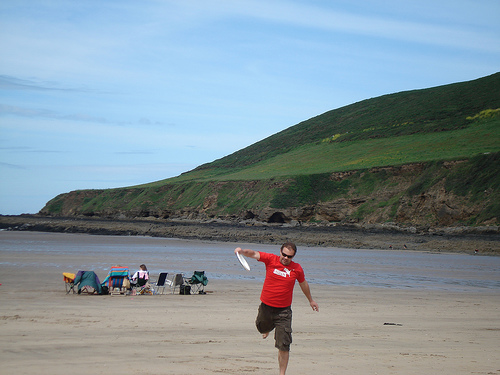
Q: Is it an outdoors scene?
A: Yes, it is outdoors.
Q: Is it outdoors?
A: Yes, it is outdoors.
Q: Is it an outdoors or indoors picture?
A: It is outdoors.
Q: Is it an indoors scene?
A: No, it is outdoors.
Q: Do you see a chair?
A: Yes, there is a chair.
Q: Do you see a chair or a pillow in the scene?
A: Yes, there is a chair.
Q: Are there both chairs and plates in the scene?
A: No, there is a chair but no plates.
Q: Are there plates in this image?
A: No, there are no plates.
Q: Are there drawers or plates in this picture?
A: No, there are no plates or drawers.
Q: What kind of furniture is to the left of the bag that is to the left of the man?
A: The piece of furniture is a chair.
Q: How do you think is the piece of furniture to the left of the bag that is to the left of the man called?
A: The piece of furniture is a chair.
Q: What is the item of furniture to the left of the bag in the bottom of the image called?
A: The piece of furniture is a chair.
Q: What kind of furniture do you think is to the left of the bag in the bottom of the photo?
A: The piece of furniture is a chair.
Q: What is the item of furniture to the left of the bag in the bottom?
A: The piece of furniture is a chair.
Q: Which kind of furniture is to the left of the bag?
A: The piece of furniture is a chair.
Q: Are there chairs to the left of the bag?
A: Yes, there is a chair to the left of the bag.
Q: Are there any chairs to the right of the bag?
A: No, the chair is to the left of the bag.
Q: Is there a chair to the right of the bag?
A: No, the chair is to the left of the bag.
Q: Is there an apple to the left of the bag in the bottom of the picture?
A: No, there is a chair to the left of the bag.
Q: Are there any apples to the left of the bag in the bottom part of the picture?
A: No, there is a chair to the left of the bag.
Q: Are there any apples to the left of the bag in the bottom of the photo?
A: No, there is a chair to the left of the bag.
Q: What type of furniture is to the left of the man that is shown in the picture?
A: The piece of furniture is a chair.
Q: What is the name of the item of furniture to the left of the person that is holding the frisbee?
A: The piece of furniture is a chair.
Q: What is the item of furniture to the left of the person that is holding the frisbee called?
A: The piece of furniture is a chair.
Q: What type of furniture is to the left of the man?
A: The piece of furniture is a chair.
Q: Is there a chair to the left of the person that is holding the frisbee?
A: Yes, there is a chair to the left of the man.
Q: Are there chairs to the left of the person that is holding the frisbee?
A: Yes, there is a chair to the left of the man.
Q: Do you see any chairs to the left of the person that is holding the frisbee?
A: Yes, there is a chair to the left of the man.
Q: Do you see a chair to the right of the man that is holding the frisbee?
A: No, the chair is to the left of the man.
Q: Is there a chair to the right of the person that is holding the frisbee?
A: No, the chair is to the left of the man.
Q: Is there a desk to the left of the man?
A: No, there is a chair to the left of the man.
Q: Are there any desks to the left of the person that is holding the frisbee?
A: No, there is a chair to the left of the man.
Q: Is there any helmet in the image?
A: No, there are no helmets.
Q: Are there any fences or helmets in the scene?
A: No, there are no helmets or fences.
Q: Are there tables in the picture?
A: No, there are no tables.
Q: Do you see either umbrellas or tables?
A: No, there are no tables or umbrellas.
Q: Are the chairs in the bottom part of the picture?
A: Yes, the chairs are in the bottom of the image.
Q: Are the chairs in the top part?
A: No, the chairs are in the bottom of the image.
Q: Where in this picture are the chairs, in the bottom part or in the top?
A: The chairs are in the bottom of the image.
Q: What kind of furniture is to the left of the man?
A: The pieces of furniture are chairs.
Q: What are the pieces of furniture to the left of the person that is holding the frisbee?
A: The pieces of furniture are chairs.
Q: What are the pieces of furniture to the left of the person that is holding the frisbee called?
A: The pieces of furniture are chairs.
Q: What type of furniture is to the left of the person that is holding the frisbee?
A: The pieces of furniture are chairs.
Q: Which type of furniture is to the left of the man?
A: The pieces of furniture are chairs.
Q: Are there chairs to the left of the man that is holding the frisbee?
A: Yes, there are chairs to the left of the man.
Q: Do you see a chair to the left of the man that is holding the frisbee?
A: Yes, there are chairs to the left of the man.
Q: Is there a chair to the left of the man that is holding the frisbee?
A: Yes, there are chairs to the left of the man.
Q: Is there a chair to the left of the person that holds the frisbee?
A: Yes, there are chairs to the left of the man.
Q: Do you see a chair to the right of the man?
A: No, the chairs are to the left of the man.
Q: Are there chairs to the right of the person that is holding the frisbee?
A: No, the chairs are to the left of the man.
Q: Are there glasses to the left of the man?
A: No, there are chairs to the left of the man.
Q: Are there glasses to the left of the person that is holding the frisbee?
A: No, there are chairs to the left of the man.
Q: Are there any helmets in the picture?
A: No, there are no helmets.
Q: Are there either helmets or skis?
A: No, there are no helmets or skis.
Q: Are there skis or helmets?
A: No, there are no helmets or skis.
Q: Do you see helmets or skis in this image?
A: No, there are no helmets or skis.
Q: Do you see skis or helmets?
A: No, there are no helmets or skis.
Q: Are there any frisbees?
A: Yes, there is a frisbee.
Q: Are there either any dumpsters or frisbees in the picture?
A: Yes, there is a frisbee.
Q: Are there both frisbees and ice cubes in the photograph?
A: No, there is a frisbee but no ice cubes.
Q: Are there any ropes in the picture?
A: No, there are no ropes.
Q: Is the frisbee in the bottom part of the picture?
A: Yes, the frisbee is in the bottom of the image.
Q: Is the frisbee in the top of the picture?
A: No, the frisbee is in the bottom of the image.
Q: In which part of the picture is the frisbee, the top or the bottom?
A: The frisbee is in the bottom of the image.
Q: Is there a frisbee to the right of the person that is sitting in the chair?
A: Yes, there is a frisbee to the right of the person.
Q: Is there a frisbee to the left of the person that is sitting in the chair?
A: No, the frisbee is to the right of the person.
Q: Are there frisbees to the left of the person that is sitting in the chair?
A: No, the frisbee is to the right of the person.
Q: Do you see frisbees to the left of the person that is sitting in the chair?
A: No, the frisbee is to the right of the person.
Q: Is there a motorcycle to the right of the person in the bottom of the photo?
A: No, there is a frisbee to the right of the person.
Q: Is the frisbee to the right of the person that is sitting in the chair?
A: Yes, the frisbee is to the right of the person.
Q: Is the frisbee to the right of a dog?
A: No, the frisbee is to the right of the person.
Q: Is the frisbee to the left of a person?
A: No, the frisbee is to the right of a person.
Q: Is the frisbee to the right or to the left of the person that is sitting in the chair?
A: The frisbee is to the right of the person.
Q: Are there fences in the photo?
A: No, there are no fences.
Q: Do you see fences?
A: No, there are no fences.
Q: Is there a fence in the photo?
A: No, there are no fences.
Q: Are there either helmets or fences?
A: No, there are no fences or helmets.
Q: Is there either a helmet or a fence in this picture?
A: No, there are no fences or helmets.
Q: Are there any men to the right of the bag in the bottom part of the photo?
A: Yes, there is a man to the right of the bag.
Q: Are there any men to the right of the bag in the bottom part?
A: Yes, there is a man to the right of the bag.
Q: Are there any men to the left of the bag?
A: No, the man is to the right of the bag.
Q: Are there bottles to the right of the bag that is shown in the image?
A: No, there is a man to the right of the bag.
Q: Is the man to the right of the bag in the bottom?
A: Yes, the man is to the right of the bag.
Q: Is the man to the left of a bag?
A: No, the man is to the right of a bag.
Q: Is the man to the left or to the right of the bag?
A: The man is to the right of the bag.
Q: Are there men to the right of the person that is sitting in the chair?
A: Yes, there is a man to the right of the person.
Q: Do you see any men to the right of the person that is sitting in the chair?
A: Yes, there is a man to the right of the person.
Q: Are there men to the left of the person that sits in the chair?
A: No, the man is to the right of the person.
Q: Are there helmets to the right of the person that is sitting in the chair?
A: No, there is a man to the right of the person.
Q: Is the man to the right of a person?
A: Yes, the man is to the right of a person.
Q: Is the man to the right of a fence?
A: No, the man is to the right of a person.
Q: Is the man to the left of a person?
A: No, the man is to the right of a person.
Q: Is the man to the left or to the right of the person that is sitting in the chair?
A: The man is to the right of the person.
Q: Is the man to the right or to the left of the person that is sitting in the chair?
A: The man is to the right of the person.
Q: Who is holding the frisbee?
A: The man is holding the frisbee.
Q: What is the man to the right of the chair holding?
A: The man is holding the frisbee.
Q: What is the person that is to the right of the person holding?
A: The man is holding the frisbee.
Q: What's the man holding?
A: The man is holding the frisbee.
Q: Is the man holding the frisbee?
A: Yes, the man is holding the frisbee.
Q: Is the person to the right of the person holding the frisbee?
A: Yes, the man is holding the frisbee.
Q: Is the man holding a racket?
A: No, the man is holding the frisbee.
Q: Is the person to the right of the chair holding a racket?
A: No, the man is holding the frisbee.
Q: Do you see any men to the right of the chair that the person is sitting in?
A: Yes, there is a man to the right of the chair.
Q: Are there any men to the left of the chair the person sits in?
A: No, the man is to the right of the chair.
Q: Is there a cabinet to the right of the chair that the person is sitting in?
A: No, there is a man to the right of the chair.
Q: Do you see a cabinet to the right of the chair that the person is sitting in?
A: No, there is a man to the right of the chair.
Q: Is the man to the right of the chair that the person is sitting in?
A: Yes, the man is to the right of the chair.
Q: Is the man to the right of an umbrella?
A: No, the man is to the right of the chair.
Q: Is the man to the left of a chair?
A: No, the man is to the right of a chair.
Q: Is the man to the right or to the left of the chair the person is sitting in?
A: The man is to the right of the chair.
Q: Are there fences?
A: No, there are no fences.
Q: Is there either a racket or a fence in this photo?
A: No, there are no fences or rackets.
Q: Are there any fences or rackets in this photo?
A: No, there are no fences or rackets.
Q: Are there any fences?
A: No, there are no fences.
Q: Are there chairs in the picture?
A: Yes, there is a chair.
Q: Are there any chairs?
A: Yes, there is a chair.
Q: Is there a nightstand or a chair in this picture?
A: Yes, there is a chair.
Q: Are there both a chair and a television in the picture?
A: No, there is a chair but no televisions.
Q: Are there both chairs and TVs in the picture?
A: No, there is a chair but no televisions.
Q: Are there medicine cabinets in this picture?
A: No, there are no medicine cabinets.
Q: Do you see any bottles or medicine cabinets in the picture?
A: No, there are no medicine cabinets or bottles.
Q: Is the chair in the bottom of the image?
A: Yes, the chair is in the bottom of the image.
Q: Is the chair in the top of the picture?
A: No, the chair is in the bottom of the image.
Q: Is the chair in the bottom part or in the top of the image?
A: The chair is in the bottom of the image.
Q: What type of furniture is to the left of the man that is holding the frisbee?
A: The piece of furniture is a chair.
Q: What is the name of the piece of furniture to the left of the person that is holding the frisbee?
A: The piece of furniture is a chair.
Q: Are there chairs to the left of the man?
A: Yes, there is a chair to the left of the man.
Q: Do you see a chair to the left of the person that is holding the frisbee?
A: Yes, there is a chair to the left of the man.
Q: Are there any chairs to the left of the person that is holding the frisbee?
A: Yes, there is a chair to the left of the man.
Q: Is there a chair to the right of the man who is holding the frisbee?
A: No, the chair is to the left of the man.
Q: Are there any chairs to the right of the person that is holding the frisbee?
A: No, the chair is to the left of the man.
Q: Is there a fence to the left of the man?
A: No, there is a chair to the left of the man.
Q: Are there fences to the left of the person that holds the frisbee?
A: No, there is a chair to the left of the man.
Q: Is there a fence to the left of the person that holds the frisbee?
A: No, there is a chair to the left of the man.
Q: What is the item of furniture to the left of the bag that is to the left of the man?
A: The piece of furniture is a chair.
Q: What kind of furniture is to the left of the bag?
A: The piece of furniture is a chair.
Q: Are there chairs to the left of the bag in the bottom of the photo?
A: Yes, there is a chair to the left of the bag.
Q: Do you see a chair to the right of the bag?
A: No, the chair is to the left of the bag.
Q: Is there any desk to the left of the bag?
A: No, there is a chair to the left of the bag.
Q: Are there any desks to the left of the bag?
A: No, there is a chair to the left of the bag.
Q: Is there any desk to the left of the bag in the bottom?
A: No, there is a chair to the left of the bag.